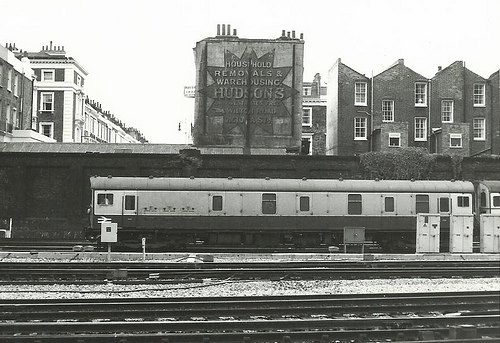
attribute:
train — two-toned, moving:
[70, 163, 487, 251]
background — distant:
[2, 38, 152, 146]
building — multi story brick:
[324, 58, 497, 245]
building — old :
[201, 38, 301, 148]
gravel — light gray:
[216, 266, 291, 295]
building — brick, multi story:
[422, 59, 499, 166]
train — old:
[103, 175, 488, 264]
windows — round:
[112, 190, 455, 217]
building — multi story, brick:
[331, 60, 497, 157]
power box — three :
[410, 207, 445, 256]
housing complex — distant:
[324, 62, 498, 162]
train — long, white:
[86, 175, 499, 249]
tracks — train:
[173, 284, 459, 327]